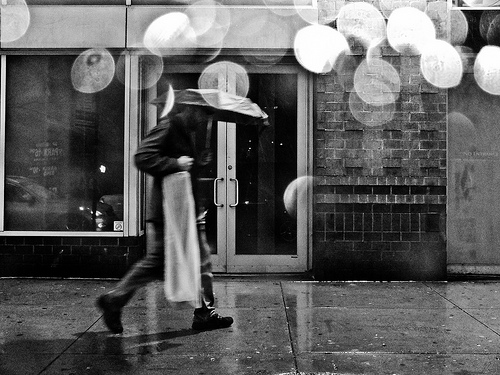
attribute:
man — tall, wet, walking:
[102, 96, 237, 374]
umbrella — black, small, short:
[146, 83, 267, 130]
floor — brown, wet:
[3, 274, 499, 370]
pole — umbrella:
[194, 118, 221, 186]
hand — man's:
[169, 149, 196, 175]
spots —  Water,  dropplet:
[294, 0, 497, 129]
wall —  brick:
[312, 49, 445, 279]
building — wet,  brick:
[2, 5, 497, 278]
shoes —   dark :
[96, 293, 232, 336]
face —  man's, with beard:
[189, 107, 212, 136]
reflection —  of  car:
[2, 173, 115, 230]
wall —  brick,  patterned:
[316, 54, 454, 278]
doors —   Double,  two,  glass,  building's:
[141, 61, 311, 276]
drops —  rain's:
[290, 2, 496, 126]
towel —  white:
[162, 170, 199, 310]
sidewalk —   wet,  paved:
[2, 282, 484, 372]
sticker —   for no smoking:
[112, 218, 122, 230]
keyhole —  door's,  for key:
[227, 162, 232, 171]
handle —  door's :
[228, 176, 242, 206]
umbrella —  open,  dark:
[148, 86, 267, 163]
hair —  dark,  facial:
[185, 115, 209, 133]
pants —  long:
[109, 220, 213, 315]